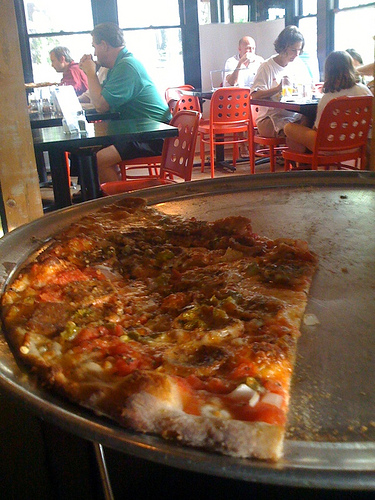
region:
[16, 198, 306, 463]
the pizza is half eaten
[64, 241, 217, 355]
red toppings are on the pizza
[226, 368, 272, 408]
onion is on the pizza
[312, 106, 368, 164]
the chair is red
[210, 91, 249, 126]
the chair has holes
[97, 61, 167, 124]
the shirt is blue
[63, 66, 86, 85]
the shirt is red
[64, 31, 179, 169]
the man is in shorts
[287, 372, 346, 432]
bread crums are on the tray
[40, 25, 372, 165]
the people are in a restaraunt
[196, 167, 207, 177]
this is the floor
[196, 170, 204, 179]
the floor is made of tiles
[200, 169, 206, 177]
the tiles are cream in color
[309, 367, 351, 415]
this is a tray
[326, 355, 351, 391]
the tray is metallic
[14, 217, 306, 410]
this is a pizza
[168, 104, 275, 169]
these are the chairs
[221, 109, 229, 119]
the chair is red in color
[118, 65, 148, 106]
the t-shirt is green in color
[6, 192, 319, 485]
3 slices of pizza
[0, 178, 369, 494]
slices of pizza on a tray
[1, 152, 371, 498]
a metal pizza tray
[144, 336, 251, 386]
a slice of pepperoni on a pizza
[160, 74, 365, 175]
several red chairs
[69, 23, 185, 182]
a person sitting at a bar waiting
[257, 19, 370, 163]
people eating together at a table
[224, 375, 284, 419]
chopped onions on a pizza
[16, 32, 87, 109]
a person sitting in front of a pizza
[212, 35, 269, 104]
a man wiping his face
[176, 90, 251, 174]
the chairs are red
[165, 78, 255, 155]
the chairs are red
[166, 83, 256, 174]
the chairs are red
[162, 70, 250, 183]
the chairs are red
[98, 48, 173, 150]
the shirt is green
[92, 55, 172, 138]
the shirt is green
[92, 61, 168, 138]
the shirt is green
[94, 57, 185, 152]
the shirt is green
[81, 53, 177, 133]
the shirt is green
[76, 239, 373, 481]
a slice of pizza on a pan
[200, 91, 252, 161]
a red plastic chair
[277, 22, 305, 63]
a woman with short hair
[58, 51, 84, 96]
a man wearing a red shirt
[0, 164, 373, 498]
a silver serving trey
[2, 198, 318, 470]
couple slices of pizza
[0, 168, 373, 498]
slices of pizza on a silver trey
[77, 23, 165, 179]
a man wearing a green shirt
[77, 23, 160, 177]
a man wearing shorts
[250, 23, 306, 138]
a woman wearing a white shirt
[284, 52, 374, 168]
a little girl in a white shirt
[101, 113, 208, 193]
an orange chair with a pattern of holes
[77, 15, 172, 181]
a man sitting on a chair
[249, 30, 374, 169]
two people sitting at a table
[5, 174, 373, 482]
a pizza that has been partially eaten.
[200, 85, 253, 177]
a red metal chair that has cut out circles on the back of it.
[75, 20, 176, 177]
a man sitting in a green shirt with dark shorts.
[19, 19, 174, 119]
a man eyeing the pizza at the next table.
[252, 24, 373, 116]
a family having lunch at a restaurant.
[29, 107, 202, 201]
a red chair and a black wood table.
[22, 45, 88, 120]
a man with a red shirt that had a pizza in front of him.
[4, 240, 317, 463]
a part of a pizza with everything on it.